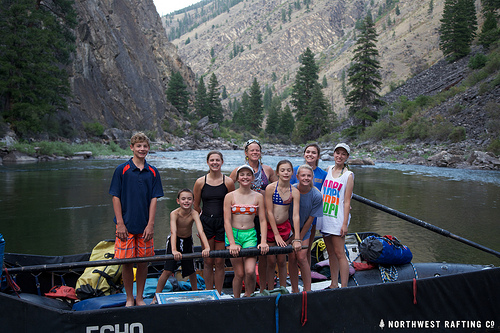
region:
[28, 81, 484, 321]
a group of people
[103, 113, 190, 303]
this is a boy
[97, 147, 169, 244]
boy wearing a blue shirt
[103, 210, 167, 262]
boy wearing orange shorts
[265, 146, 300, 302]
this is a girll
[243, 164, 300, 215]
girl wearing a bikini top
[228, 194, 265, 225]
girl wearing a tube top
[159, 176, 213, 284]
this is a little boy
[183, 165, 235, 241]
woman wearing a black shirt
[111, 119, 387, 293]
a group of people smiling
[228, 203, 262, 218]
orange and white polka dotted bikini top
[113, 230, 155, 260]
orange and blue checkered shorts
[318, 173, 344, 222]
multi-colored letters on white tank top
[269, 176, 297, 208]
American flag bikini top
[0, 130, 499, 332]
large group on dark gray raft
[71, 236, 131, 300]
yellow and black duffel bag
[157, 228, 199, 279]
black swim trunks with white drawstrings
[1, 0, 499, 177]
rocky mountains behind water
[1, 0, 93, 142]
green vegetation growing on rocky mountain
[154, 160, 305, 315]
three people holding black oar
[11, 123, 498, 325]
they are standing on a boat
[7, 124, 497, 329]
they are standing on a raft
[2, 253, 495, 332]
this is a rubber raft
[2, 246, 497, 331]
the raft is black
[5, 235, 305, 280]
this is the handle to a paddle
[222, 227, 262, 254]
her shorts are bright green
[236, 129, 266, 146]
sunglasses on a woman's head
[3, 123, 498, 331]
they are in a river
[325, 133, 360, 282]
she is wearing a baseball cap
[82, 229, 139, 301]
this is a large yellow duffel bag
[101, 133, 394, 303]
people standing on a raft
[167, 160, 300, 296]
boy and two girls are resting arms on an oar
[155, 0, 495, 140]
trees along a hill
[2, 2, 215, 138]
a large mountain made from stone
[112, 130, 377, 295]
people standing in their bathing suits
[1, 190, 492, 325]
a black raft with black oars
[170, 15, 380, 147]
evergreen trees behind the people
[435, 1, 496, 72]
trees growing on side of the mountain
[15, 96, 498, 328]
raft is near the shore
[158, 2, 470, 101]
the side of a mountain with just a few trees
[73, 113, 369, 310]
a group of people on a boat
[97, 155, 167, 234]
a blue polo shirt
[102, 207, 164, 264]
a pair of orange shorts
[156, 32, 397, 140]
a cluster of evergreen trees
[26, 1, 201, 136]
the base of a rocky cliff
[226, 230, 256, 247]
a pair of green shorts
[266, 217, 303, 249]
a pair of red shorts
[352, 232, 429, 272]
a blue and black duffle bag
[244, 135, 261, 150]
a pair of sunglasses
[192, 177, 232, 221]
a black tank top